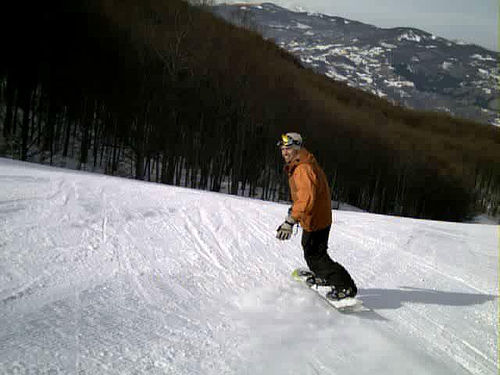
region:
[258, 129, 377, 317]
A man snowboarding down a slope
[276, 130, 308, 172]
The man is happy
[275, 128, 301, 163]
Man is wearing ski goggles on his head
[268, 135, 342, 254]
The man is wearing an orange jacket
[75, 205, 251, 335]
There are many tracks in the snow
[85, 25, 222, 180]
There are no leaves on the trees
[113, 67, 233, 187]
There are no leaves on the tress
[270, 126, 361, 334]
The man is skiing in an orange jacket and black pants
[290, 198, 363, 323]
Black pants on the boarder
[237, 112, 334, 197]
The man is having a good time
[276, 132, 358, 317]
Man snowboarding in snow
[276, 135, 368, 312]
Man standing on snowboard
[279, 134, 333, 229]
Man wearing orange jacket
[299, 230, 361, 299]
Man wearing black pants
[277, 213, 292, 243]
Man wearing grey gloves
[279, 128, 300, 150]
White and black hat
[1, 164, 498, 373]
Ground covered with snow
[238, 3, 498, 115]
Snow patches on the mountain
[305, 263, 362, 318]
White snowboard on snow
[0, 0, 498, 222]
Tall brown trees on snow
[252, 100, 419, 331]
a man on a snowboard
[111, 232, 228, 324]
tracks in the snow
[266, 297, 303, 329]
snow flying into the air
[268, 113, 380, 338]
a man wearing a brown jacket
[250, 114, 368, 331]
a ma wearing black pants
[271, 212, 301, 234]
a gray and black glove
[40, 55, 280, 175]
a line of bare trees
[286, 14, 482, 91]
a mountain behind the man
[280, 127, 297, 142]
yellow snow googgles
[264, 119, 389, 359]
a man enjoying the snow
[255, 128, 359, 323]
man snowboarding down mountain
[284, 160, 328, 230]
orange jacket of man snowboarding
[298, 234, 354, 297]
black pants of snowboarder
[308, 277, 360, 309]
white snowboard of snowboarder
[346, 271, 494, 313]
shadow of snowboarder on snow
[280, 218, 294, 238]
gray and black glove of snowboarder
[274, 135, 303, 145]
knit cap snowboarder is wearing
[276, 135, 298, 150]
ski goggles of snowboarder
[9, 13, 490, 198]
trees covering mountain side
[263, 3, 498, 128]
patches of snow on mountain in background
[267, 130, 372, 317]
man on a snowboard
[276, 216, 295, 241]
a man's gloved hand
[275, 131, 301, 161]
the head of a man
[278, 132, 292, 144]
snow goggles on a man's head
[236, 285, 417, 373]
mists of snow in the air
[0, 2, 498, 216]
a wide expanse of trees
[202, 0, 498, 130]
cliff face in the distance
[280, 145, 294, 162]
face of a man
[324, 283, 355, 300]
snow boot clipped into a board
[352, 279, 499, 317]
shadow of a man snowboarding